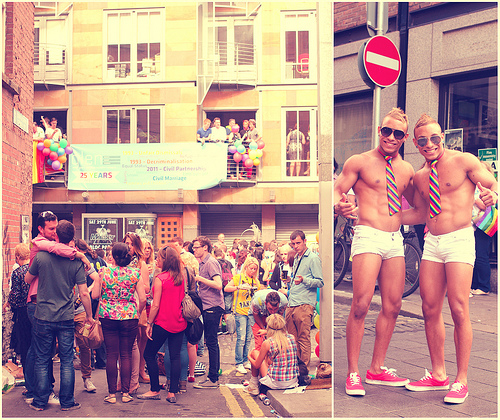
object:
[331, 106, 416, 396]
men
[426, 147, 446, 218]
neckties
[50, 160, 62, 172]
balloons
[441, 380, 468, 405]
shoes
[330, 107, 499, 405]
couples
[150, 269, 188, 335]
shirt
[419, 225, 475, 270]
shorts